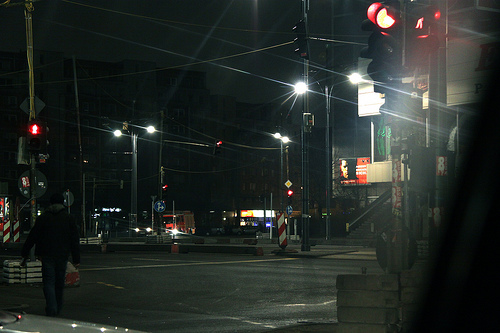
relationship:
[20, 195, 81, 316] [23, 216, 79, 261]
man wearing jacket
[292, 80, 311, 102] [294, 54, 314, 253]
light on pole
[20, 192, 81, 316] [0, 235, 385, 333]
man crossing road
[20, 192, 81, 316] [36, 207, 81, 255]
man wearing jacket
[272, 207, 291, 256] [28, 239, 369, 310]
flags on street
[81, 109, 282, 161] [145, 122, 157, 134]
lines under lamp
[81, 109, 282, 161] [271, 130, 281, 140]
lines under lamp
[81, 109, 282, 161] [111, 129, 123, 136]
lines under lamp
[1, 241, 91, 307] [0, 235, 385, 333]
cement barriers on road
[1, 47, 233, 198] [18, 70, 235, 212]
buildings with windows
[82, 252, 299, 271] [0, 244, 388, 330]
lines painted on street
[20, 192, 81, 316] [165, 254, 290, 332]
man crossing street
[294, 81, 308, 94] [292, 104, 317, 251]
light on pole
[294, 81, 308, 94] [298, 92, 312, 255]
light on pole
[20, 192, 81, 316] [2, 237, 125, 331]
man standing on corner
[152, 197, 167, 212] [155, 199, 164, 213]
sign with arrows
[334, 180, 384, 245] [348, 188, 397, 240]
staircase with balustrade